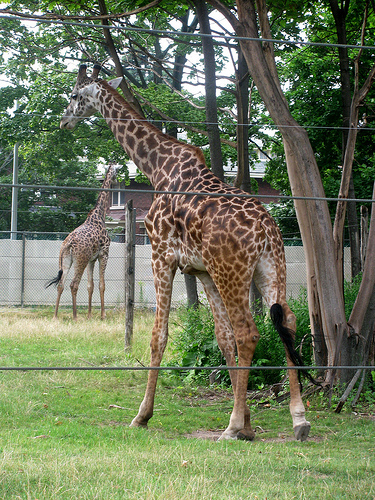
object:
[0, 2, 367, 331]
trees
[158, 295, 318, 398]
bush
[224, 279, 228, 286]
spot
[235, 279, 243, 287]
spot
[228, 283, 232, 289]
spot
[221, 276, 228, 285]
spot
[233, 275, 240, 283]
spot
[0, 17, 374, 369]
fence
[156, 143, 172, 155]
spots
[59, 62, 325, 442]
animal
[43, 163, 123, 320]
animal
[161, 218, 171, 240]
dark spots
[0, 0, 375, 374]
enclosure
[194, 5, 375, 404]
tree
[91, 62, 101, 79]
horn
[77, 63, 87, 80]
horn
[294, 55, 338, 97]
leaves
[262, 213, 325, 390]
tail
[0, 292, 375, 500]
field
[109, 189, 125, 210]
window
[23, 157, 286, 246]
house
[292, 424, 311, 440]
giraffe hoof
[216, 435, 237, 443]
giraffe hoof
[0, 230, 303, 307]
fence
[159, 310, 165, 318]
spots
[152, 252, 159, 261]
dark spots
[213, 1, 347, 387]
edge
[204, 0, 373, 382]
stem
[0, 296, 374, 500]
grass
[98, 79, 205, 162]
mane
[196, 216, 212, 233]
spots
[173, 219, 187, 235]
spots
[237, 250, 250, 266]
spots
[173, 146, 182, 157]
spots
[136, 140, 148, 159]
spots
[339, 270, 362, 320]
bush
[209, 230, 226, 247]
dark spot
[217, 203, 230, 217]
dark spot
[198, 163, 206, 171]
dark spot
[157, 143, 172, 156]
dark spot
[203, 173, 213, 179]
dark spot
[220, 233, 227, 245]
spot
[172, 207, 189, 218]
spot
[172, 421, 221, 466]
part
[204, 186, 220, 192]
spots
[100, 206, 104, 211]
spots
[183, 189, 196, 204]
dark spots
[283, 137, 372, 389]
trunk